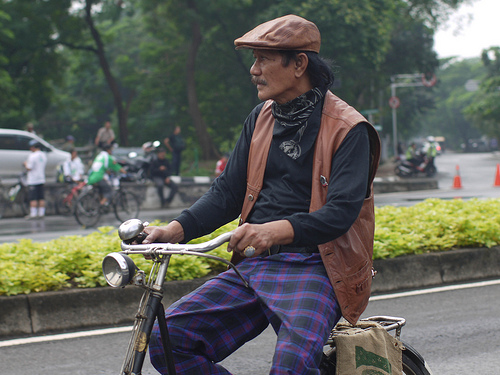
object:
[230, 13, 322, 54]
hat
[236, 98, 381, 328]
vest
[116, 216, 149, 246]
bell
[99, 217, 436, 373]
bike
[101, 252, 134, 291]
light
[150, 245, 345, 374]
pants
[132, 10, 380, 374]
man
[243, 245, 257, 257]
ring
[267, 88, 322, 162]
scarf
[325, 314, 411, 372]
bag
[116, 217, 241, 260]
handle bars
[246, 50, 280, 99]
face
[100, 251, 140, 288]
headlight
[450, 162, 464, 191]
cone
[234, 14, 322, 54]
cap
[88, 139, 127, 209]
person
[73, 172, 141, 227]
bike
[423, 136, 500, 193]
street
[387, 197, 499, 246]
plants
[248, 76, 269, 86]
moustache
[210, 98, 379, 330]
jacket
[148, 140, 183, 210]
people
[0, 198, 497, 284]
bush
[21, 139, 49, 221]
kids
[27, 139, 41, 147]
helmets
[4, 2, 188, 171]
trees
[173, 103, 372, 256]
shirt